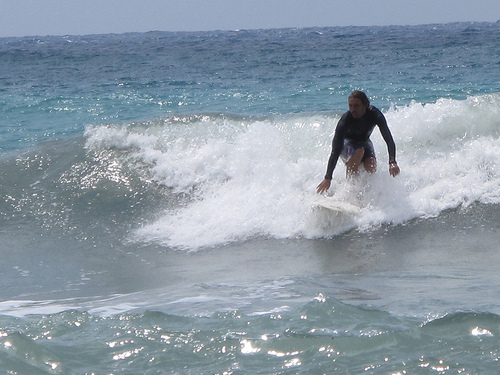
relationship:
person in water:
[317, 88, 403, 201] [13, 20, 486, 374]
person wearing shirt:
[317, 88, 403, 201] [322, 100, 400, 181]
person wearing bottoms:
[317, 88, 403, 201] [332, 137, 381, 168]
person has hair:
[317, 88, 403, 201] [346, 90, 372, 111]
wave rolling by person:
[80, 91, 499, 242] [317, 88, 403, 201]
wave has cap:
[80, 91, 499, 242] [85, 89, 498, 256]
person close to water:
[317, 88, 403, 201] [13, 20, 486, 374]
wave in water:
[80, 91, 499, 242] [13, 20, 486, 374]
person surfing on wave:
[317, 88, 403, 201] [80, 91, 499, 242]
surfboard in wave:
[296, 191, 375, 219] [80, 91, 499, 242]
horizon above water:
[1, 20, 499, 42] [13, 20, 486, 374]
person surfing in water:
[317, 88, 403, 201] [13, 20, 486, 374]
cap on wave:
[85, 89, 498, 256] [80, 91, 499, 242]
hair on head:
[346, 90, 372, 111] [346, 88, 371, 125]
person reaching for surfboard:
[317, 88, 403, 201] [296, 191, 375, 219]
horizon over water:
[1, 20, 499, 42] [13, 20, 486, 374]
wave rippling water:
[80, 91, 499, 242] [13, 20, 486, 374]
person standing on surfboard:
[317, 88, 403, 201] [296, 191, 375, 219]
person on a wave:
[317, 88, 403, 201] [80, 91, 499, 242]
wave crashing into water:
[80, 91, 499, 242] [13, 20, 486, 374]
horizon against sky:
[1, 20, 499, 42] [1, 1, 498, 40]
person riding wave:
[317, 88, 403, 201] [80, 91, 499, 242]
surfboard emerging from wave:
[296, 191, 375, 219] [80, 91, 499, 242]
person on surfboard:
[317, 88, 403, 201] [296, 191, 375, 219]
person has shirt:
[317, 88, 403, 201] [322, 100, 400, 181]